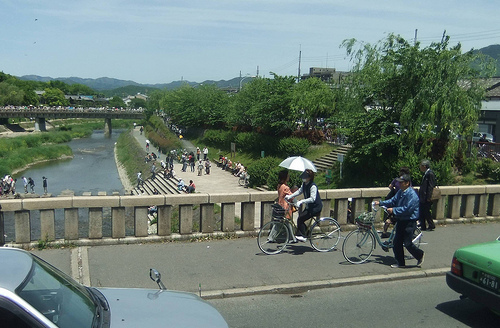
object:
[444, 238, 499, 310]
car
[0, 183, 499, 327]
bridge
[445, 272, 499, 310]
bumper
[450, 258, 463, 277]
tail light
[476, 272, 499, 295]
license plate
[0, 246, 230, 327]
car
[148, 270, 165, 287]
side mirror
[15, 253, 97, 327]
windshield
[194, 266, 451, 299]
curb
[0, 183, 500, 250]
safety railing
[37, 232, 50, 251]
weeds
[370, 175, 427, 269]
man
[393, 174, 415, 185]
cap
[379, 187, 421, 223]
jacket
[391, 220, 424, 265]
pants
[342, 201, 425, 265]
bike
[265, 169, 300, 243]
woman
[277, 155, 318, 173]
umbrella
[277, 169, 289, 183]
hair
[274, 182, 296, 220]
tunic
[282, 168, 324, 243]
woman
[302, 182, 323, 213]
vest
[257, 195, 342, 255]
bike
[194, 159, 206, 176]
crowd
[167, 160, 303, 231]
landing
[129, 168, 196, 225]
stairs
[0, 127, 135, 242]
river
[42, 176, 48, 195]
person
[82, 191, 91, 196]
stones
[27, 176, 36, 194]
person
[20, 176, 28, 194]
person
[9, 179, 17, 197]
person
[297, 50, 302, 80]
power pole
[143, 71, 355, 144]
trees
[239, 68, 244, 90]
power pole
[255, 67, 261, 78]
power pole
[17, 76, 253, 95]
mountains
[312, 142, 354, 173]
stairs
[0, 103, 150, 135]
bridge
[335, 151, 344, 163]
sign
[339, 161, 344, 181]
post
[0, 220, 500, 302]
sidewalk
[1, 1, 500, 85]
sky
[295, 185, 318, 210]
sleeve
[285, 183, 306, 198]
sleeve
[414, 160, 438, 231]
man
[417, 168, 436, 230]
suit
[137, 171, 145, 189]
person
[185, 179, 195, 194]
person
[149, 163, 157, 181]
person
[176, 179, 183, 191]
person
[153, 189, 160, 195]
person